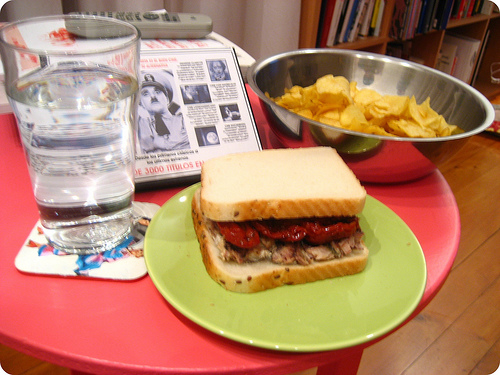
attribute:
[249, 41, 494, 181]
bowl — metal, stainless steel, silver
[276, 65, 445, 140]
chips — plain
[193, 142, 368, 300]
sandwich — white bread, chicken, white, delicious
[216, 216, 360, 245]
peppers — red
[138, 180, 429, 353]
plate — green, light green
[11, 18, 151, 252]
glass — tall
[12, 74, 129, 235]
water — cold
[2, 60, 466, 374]
table — red, pink, wooden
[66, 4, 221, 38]
remote — gray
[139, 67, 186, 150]
picture — charlie chaplin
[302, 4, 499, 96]
bookcase — wooden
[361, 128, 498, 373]
floor — hardwood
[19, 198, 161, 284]
coaster — white